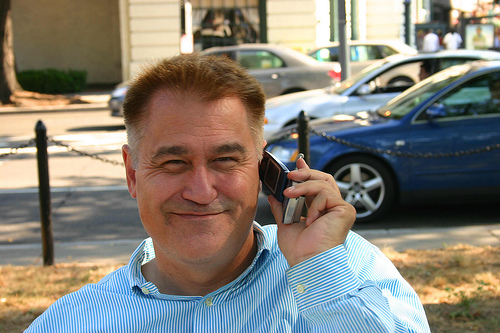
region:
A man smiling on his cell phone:
[88, 50, 360, 310]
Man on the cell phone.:
[17, 48, 441, 332]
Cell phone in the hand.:
[257, 140, 318, 232]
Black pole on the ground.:
[27, 116, 61, 272]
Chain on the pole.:
[0, 123, 126, 175]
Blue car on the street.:
[270, 54, 499, 235]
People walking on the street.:
[417, 20, 462, 55]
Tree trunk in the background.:
[0, 0, 31, 107]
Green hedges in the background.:
[12, 62, 89, 95]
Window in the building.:
[177, 2, 269, 52]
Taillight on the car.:
[324, 65, 342, 83]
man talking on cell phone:
[100, 82, 255, 274]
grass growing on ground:
[12, 256, 96, 318]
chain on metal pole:
[66, 138, 116, 178]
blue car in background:
[288, 57, 498, 244]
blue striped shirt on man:
[2, 245, 348, 316]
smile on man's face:
[164, 198, 237, 249]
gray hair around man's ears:
[123, 121, 157, 174]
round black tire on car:
[304, 128, 387, 235]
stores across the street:
[105, 8, 498, 95]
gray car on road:
[97, 32, 334, 119]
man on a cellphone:
[20, 58, 428, 329]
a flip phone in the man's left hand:
[259, 149, 356, 256]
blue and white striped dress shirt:
[23, 225, 432, 331]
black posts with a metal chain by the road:
[0, 108, 498, 265]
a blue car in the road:
[269, 58, 499, 218]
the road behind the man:
[1, 111, 498, 244]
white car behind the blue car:
[265, 51, 498, 141]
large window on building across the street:
[186, 0, 264, 49]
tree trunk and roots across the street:
[1, 3, 57, 103]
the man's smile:
[164, 206, 229, 218]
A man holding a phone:
[22, 52, 434, 332]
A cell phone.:
[259, 151, 304, 226]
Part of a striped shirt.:
[88, 303, 124, 324]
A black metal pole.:
[30, 119, 58, 264]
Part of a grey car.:
[291, 67, 323, 87]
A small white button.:
[296, 283, 303, 292]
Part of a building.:
[141, 12, 166, 33]